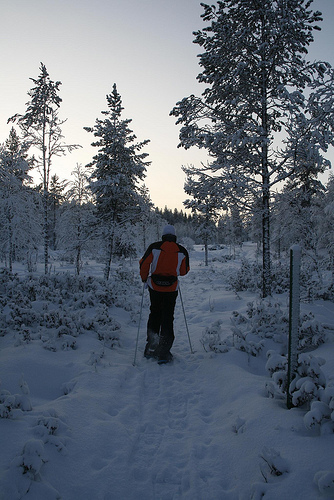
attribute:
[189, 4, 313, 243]
tree — snow covered, tall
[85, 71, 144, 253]
tree — snow covered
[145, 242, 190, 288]
jacket — orange, black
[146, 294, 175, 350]
pants — black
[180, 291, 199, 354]
ski pole — black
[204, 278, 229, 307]
snow — white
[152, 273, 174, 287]
fanny pack — black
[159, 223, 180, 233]
hat — white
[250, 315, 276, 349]
shrub — snow covered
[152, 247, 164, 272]
parka — orange, white, black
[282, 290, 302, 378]
pole — snow covered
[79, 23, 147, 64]
sky — grey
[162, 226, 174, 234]
cap — white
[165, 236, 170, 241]
pompom — black